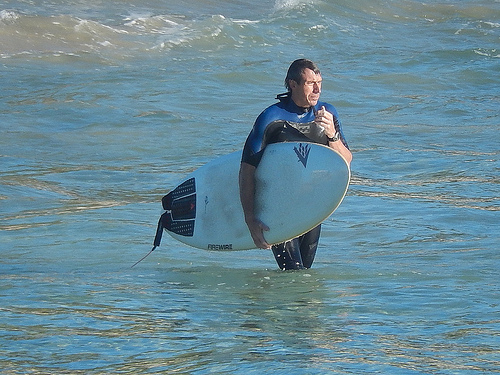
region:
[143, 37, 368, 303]
man in the water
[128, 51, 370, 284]
man wearing a water suit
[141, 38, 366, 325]
man holding a surf board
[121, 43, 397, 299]
man wearing a watch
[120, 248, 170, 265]
cord on surf board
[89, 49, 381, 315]
man looking in the sun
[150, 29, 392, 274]
A man holding a surfboard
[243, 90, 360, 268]
A blue and black wetsuit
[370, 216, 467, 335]
Waters in the sea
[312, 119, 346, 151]
A wrist watch in the photo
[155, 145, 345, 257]
A white surfboard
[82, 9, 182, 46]
Waves in the water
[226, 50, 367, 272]
A man wading in the water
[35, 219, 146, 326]
Calm waters in the sea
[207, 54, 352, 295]
A man in the water holding a surfboard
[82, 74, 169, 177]
Blue waters in the sea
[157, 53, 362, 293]
surfer carrying white board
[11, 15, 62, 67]
white and gray ocean waves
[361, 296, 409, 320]
white and gray ocean waves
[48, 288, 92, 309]
white and gray ocean waves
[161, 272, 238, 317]
white and gray ocean waves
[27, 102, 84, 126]
white and gray ocean waves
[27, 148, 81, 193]
white and gray ocean waves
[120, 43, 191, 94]
white and gray ocean waves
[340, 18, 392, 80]
white and gray ocean waves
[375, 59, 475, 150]
white and gray ocean waves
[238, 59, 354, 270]
surfer is walking in the water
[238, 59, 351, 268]
surfer is holding a surfboard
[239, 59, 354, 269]
surfer is a white man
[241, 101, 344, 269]
surfer has on a wet suit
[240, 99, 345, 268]
wet suit is black and blue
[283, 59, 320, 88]
surfer has wet brown hair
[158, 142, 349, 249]
surfboard is black and white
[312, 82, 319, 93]
surfer has a white nose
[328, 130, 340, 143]
surfer has on a gray and black watch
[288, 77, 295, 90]
surfer has an ear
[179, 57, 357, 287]
surfer carrying board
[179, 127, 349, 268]
white surfboard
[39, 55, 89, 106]
white and gray ocean waves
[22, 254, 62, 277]
white and gray ocean waves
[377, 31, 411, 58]
white and gray ocean waves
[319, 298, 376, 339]
white and gray ocean waves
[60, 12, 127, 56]
white and gray ocean waves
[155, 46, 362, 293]
surfer carrying white board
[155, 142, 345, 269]
white colored surf board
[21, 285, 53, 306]
white and gray ripples in water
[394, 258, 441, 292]
white and gray ripples in water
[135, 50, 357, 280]
man carrying surfboard through water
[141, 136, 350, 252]
blue and white surfboard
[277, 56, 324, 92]
wet brown hair on man's head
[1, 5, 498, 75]
wave building behind man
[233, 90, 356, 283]
black and blue wet suit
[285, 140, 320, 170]
blue logo on surfboard